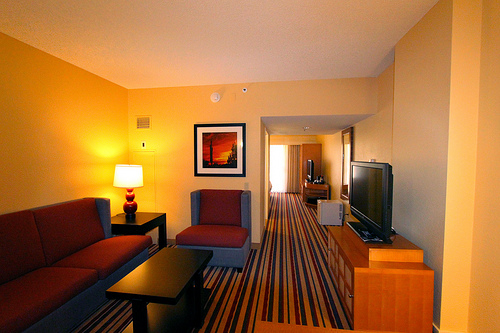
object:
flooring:
[73, 190, 352, 333]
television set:
[348, 161, 393, 243]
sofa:
[0, 198, 152, 330]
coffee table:
[107, 248, 215, 332]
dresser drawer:
[328, 223, 436, 332]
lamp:
[112, 164, 144, 218]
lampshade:
[113, 164, 144, 189]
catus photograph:
[194, 124, 244, 177]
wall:
[0, 29, 126, 214]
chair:
[176, 189, 252, 268]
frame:
[193, 123, 245, 177]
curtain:
[287, 145, 300, 192]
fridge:
[317, 200, 343, 225]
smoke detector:
[210, 92, 220, 102]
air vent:
[137, 117, 150, 128]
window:
[269, 145, 287, 192]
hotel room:
[0, 0, 500, 332]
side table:
[109, 213, 167, 248]